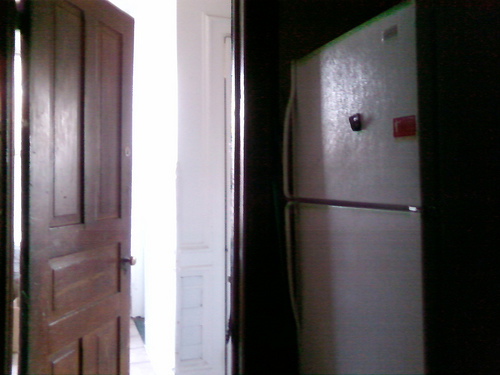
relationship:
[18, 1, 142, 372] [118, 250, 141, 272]
door has doorknob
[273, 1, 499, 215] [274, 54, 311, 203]
freezer has handle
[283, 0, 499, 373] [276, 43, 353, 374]
freezer has shadow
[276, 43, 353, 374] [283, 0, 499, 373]
shadow on freezer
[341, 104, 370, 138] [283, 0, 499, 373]
magnet on freezer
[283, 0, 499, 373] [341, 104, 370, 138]
freezer has magnet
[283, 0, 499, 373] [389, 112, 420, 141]
freezer has magnet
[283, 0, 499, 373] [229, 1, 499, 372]
freezer in room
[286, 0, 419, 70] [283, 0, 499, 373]
line on freezer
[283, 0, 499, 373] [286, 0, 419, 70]
freezer has line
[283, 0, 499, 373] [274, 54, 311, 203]
freezer has handle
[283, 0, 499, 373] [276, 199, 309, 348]
freezer has handle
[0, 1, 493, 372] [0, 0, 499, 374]
picture taken in room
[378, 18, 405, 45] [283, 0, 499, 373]
decal on freezer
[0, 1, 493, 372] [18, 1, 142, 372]
picture has door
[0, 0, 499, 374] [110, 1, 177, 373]
room has wall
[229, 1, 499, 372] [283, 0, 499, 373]
room has freezer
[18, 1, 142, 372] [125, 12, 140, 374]
door has edge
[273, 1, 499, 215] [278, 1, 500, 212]
freezer has door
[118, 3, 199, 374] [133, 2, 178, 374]
doorway has light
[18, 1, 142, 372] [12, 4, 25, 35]
door has hinge